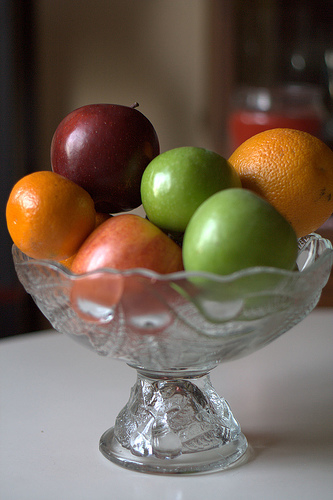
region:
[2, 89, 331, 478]
A glass dish full of fruit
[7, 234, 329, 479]
A clear glass dish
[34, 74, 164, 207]
A red apple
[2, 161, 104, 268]
A orange tangerine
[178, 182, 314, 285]
A green apple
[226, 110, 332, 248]
A orange colored orange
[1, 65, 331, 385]
A bowl of colorful fruit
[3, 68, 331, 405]
A dish full of mixed fruit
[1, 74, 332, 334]
A assortment of colorful fruits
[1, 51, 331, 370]
A dish of apples and oranges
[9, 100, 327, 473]
glass bowl filled with fruit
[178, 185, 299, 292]
round green apple without a stem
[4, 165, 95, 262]
orange with flat spot on left side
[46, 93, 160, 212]
red apple with stem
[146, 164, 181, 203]
reflection of light in fruit skin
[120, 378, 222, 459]
ornamental etching in bowl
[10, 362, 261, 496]
white table top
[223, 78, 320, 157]
red candle behind bowl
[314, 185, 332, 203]
black spot on orange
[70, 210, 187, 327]
pink apple in bowl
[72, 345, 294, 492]
bottom of crystal bowl on white table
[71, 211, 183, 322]
red apple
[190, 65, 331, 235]
candle behind fruit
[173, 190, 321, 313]
granny smith apple in crystal bowl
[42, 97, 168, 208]
dark red apple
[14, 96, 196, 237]
dark red apple on top of an orange and granny smith apple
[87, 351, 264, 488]
base of crystal fruit bowl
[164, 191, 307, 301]
ripe apple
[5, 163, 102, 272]
ripe orange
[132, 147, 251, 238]
shiny green apple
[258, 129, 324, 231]
This is an orange that is orange in color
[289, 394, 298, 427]
The top of this table is a bright white color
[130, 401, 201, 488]
The color of this crystal is a brilliant glass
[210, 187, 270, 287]
The apple is green in color and lovely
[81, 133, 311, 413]
This photo was taken in a restaurant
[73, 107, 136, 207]
This apple is red and it is a delicious apple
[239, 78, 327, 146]
There looks to be a candle in the background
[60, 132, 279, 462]
This photo was taken around noon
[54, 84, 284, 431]
This photo was taking in the city of Dayton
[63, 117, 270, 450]
This photo was taken in the state of Ohio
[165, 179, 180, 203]
part of an apple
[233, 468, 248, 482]
part of a table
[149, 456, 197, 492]
edge of a bus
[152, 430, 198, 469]
part of a glass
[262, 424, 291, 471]
part of a shade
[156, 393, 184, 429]
part of a glass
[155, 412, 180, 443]
part of a glass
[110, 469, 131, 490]
part of a table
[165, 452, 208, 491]
edge of a base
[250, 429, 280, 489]
part of a shade